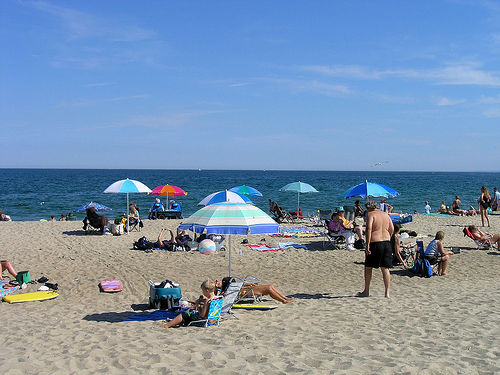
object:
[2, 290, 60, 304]
board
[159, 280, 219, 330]
boy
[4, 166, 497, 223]
water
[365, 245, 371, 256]
hand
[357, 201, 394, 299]
man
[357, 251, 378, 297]
legs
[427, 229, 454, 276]
woman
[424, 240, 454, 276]
chair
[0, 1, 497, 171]
sky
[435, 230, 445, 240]
head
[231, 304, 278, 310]
board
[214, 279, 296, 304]
person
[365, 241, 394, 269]
black shorts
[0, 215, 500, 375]
beach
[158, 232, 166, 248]
arms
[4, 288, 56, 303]
yellow boogieboard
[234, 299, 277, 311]
yellow boogieboard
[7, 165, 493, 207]
water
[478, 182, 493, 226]
woman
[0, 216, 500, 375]
sand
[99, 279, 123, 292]
board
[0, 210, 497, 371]
sand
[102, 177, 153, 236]
umbrella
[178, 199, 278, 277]
umbrella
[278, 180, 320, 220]
umbrella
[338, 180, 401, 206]
umbrella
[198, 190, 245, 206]
umbrella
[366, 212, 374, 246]
arm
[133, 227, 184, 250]
person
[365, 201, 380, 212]
head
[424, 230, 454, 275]
person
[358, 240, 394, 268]
shorts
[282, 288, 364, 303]
shadow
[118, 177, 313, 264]
umbrella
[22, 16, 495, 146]
sky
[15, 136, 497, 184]
water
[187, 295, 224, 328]
chair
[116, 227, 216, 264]
towel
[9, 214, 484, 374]
shoreline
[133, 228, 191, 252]
air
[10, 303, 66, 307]
sand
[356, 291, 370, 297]
feet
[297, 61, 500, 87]
clouds